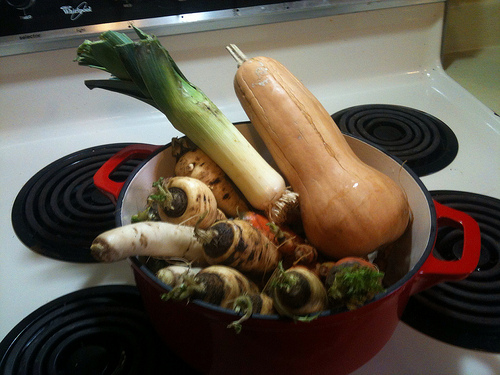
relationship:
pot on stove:
[90, 120, 480, 374] [256, 15, 498, 185]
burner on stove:
[317, 96, 465, 185] [1, 0, 499, 373]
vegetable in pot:
[70, 21, 416, 337] [115, 116, 434, 370]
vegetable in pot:
[70, 21, 416, 337] [92, 118, 481, 373]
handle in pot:
[427, 200, 484, 280] [92, 118, 481, 373]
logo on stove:
[53, 5, 95, 22] [1, 0, 499, 373]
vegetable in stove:
[152, 174, 215, 226] [8, 68, 481, 371]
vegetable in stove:
[70, 21, 416, 337] [8, 68, 481, 371]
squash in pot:
[227, 44, 430, 265] [115, 116, 434, 370]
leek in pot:
[69, 18, 299, 223] [92, 118, 481, 373]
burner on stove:
[329, 102, 458, 178] [1, 0, 499, 373]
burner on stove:
[0, 284, 178, 375] [6, 32, 493, 340]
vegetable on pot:
[70, 21, 416, 337] [92, 118, 481, 373]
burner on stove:
[18, 138, 156, 257] [1, 0, 499, 373]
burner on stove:
[3, 282, 177, 374] [1, 0, 499, 373]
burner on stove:
[398, 188, 499, 354] [1, 0, 499, 373]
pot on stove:
[59, 83, 454, 360] [8, 68, 481, 371]